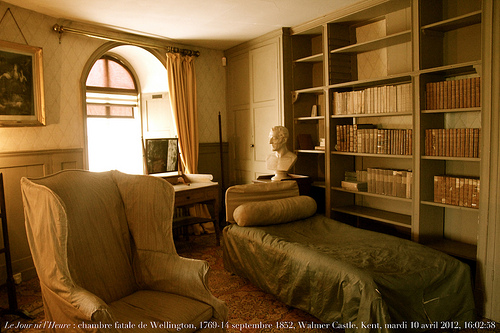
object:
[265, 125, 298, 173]
bust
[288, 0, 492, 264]
bookshelf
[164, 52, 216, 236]
curtain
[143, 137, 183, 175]
mirror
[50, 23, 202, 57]
curtain rod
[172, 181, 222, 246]
desk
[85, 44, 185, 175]
window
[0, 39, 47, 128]
framed picture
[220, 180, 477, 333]
sofa chair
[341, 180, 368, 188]
book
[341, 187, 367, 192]
book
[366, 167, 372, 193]
book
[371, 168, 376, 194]
book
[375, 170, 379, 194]
book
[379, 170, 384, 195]
book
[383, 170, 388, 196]
book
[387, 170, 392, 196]
book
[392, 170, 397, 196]
book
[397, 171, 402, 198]
book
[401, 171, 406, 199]
book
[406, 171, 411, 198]
book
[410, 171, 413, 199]
book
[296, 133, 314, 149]
book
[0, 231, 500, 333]
floor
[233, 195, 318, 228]
pillow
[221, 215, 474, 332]
cover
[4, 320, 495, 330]
text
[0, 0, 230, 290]
wall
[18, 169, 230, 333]
chair